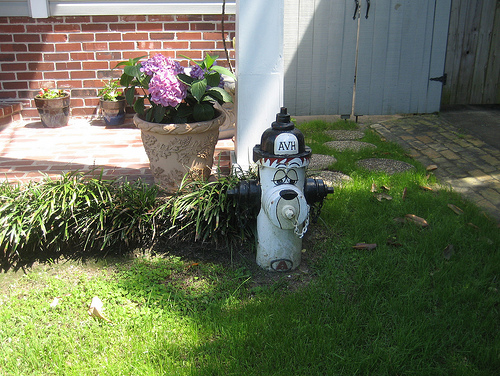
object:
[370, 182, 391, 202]
dead leaves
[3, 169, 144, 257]
grass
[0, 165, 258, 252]
bush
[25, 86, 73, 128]
pot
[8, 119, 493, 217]
patio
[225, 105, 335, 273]
fire hydrant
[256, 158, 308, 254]
dog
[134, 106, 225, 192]
pot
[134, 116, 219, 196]
pot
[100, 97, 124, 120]
pot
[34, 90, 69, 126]
pot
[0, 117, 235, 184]
patio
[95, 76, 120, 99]
plants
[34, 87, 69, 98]
plants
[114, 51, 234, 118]
plants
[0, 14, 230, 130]
wall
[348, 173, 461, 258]
leaves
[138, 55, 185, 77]
flower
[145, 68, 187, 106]
flower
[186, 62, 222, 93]
flower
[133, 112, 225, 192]
planter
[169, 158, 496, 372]
shadow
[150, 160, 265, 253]
grass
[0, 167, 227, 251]
plants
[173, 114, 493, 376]
grass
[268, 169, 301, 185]
two eyes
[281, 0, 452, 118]
door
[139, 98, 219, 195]
pot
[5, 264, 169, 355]
grass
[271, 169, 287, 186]
eye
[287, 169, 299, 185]
eye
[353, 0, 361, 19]
handle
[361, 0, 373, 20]
handle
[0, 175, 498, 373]
ground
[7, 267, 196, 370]
part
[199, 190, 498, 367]
shadow